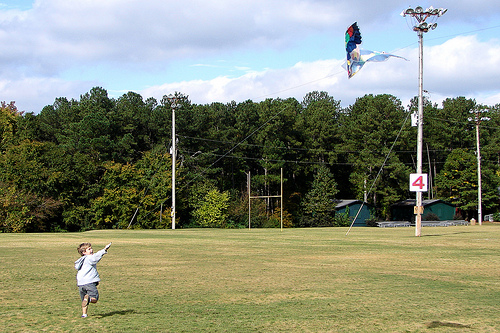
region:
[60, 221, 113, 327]
the boy in the field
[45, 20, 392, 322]
the boy flying the kite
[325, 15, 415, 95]
the kite in the sky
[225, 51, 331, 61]
the clear blue sky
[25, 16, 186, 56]
the clouds in the sky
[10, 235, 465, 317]
the field of grass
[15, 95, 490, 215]
green trees with leaves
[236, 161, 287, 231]
the goal post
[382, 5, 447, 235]
the lights above the field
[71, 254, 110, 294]
the boy wearing hoodie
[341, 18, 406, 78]
Colorful kite flying in the sky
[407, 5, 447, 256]
a light pole with a sign on it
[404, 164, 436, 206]
white sign with a red number four on it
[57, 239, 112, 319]
small boy wearing a white hoodie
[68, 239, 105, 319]
small boy with brown hair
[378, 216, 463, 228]
table and benches in the park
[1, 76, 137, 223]
group of green trees in the background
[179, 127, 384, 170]
two rows of electric wires in front of trees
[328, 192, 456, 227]
Two green buildings with gray roofs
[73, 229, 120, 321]
small boy running with arm up holding kite string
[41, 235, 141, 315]
kid flying a kite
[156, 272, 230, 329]
grass next to kid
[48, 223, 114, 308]
kid with a gray sweatshirt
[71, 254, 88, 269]
hood on back of sweatshirt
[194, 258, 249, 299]
brown grass in the field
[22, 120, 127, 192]
trees in the distance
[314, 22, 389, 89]
colorful kite above the kid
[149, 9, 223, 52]
sky above the trees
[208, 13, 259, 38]
white cloud in sky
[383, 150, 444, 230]
pole with the number four on it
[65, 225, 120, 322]
Young boy flying kite in field.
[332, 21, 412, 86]
Kite flying in air.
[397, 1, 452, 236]
Light post standing in field.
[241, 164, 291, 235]
A football goal post.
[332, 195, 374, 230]
Side of green house at end of field.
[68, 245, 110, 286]
Young boy dressed in gray sweatshirt with hood.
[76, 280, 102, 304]
Young boy dressed in gray shorts.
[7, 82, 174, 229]
Trees growing at end of field.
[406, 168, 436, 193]
Number 4 written in red on white sign.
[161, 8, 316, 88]
White and gray clouds in sky.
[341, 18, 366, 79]
Kite flying in the air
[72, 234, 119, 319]
Little boy flying a kite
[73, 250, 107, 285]
White jacket worn by little boy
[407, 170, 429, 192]
Red and white sign on pole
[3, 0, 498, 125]
Blue sky with white clouds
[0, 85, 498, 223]
Tall trees in the distance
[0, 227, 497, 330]
Grass on the field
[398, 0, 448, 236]
Field light pole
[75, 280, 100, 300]
Gray shorts little boy is wearing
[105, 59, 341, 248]
Kite string held by little boy